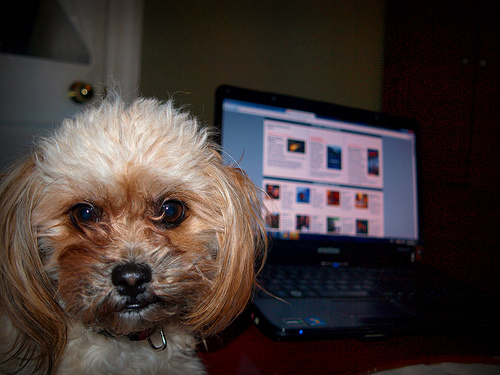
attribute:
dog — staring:
[0, 97, 262, 373]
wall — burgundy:
[135, 7, 378, 127]